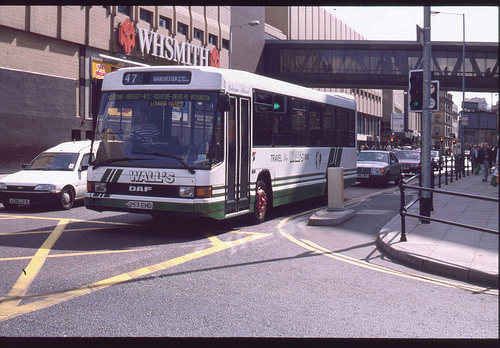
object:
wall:
[127, 169, 178, 184]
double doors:
[223, 94, 256, 220]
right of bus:
[255, 6, 491, 250]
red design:
[117, 16, 138, 57]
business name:
[133, 27, 209, 67]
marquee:
[147, 70, 195, 84]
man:
[120, 108, 166, 155]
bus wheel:
[254, 178, 274, 221]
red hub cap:
[257, 186, 271, 217]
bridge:
[254, 36, 498, 93]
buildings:
[268, 6, 385, 158]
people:
[474, 142, 498, 182]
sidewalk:
[374, 147, 499, 293]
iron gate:
[384, 146, 498, 250]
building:
[6, 6, 269, 177]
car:
[359, 149, 404, 186]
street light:
[407, 67, 425, 111]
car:
[0, 130, 100, 214]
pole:
[417, 4, 434, 225]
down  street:
[6, 178, 301, 348]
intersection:
[3, 194, 391, 347]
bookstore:
[6, 3, 227, 113]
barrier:
[326, 167, 344, 210]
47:
[126, 71, 137, 85]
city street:
[5, 154, 499, 332]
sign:
[113, 17, 231, 69]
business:
[1, 3, 312, 179]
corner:
[365, 99, 499, 322]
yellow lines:
[0, 206, 274, 332]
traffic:
[338, 129, 466, 188]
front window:
[90, 89, 226, 169]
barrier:
[401, 177, 495, 243]